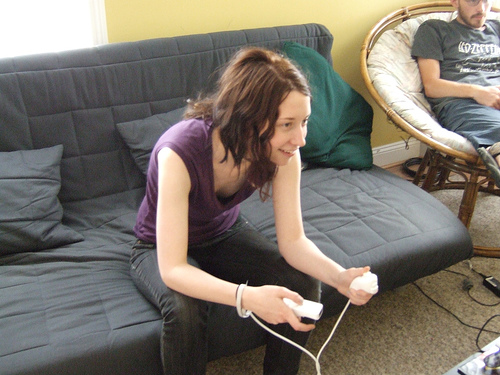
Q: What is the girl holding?
A: Wii device.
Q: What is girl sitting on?
A: Chair.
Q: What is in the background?
A: A yellow wall.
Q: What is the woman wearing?
A: A purple shirt and grey pants.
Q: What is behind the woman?
A: Pillows.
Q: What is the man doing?
A: Playing a game.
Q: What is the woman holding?
A: A Wii.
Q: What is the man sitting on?
A: A papasan chair.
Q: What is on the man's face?
A: A beard.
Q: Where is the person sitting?
A: Chair.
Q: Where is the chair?
A: Against the wall.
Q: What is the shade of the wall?
A: Yellow.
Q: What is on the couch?
A: Pillow.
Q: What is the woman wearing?
A: Purple shirt.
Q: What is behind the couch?
A: Window.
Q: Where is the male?
A: Sitting in a chair.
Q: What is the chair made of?
A: Wicker.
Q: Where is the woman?
A: On the couch.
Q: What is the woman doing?
A: Playing.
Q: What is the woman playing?
A: Video games.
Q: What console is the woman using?
A: Wii.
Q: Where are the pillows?
A: On the couch.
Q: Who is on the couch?
A: The woman.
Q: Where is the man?
A: In the chair.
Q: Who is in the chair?
A: The man.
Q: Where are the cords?
A: On the floor.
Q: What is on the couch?
A: Pillows.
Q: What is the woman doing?
A: Playing video games.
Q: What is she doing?
A: Playing game.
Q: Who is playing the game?
A: Girl.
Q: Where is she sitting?
A: Couch.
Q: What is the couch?
A: Dark blue.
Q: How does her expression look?
A: Happy.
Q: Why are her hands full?
A: Game controller.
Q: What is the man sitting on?
A: Chair.